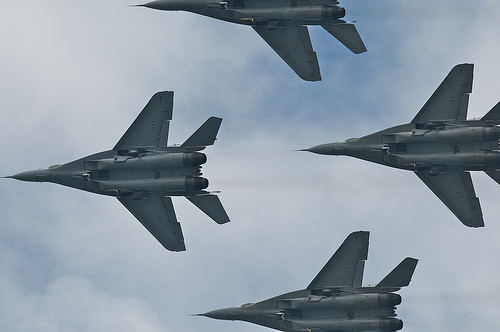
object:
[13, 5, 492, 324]
jets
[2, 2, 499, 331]
sky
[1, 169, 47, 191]
nose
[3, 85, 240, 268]
jet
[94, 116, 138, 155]
edges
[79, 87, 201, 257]
wings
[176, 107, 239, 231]
tail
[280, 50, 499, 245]
jet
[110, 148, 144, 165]
panels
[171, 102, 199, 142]
space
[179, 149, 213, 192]
engines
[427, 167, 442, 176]
wheel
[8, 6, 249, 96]
clouds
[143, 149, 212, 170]
engine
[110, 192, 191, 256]
wing